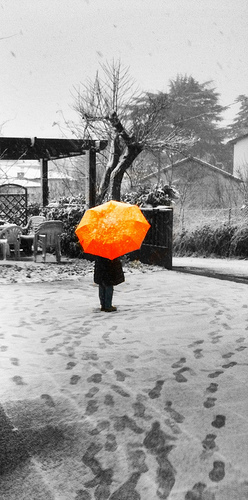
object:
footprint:
[208, 457, 227, 480]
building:
[138, 153, 243, 209]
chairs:
[1, 224, 23, 258]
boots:
[103, 303, 117, 308]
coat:
[92, 253, 125, 286]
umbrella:
[74, 197, 149, 257]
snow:
[89, 206, 125, 235]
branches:
[81, 64, 163, 145]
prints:
[208, 365, 223, 377]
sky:
[0, 1, 239, 147]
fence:
[174, 206, 246, 232]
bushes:
[172, 222, 184, 258]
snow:
[173, 255, 234, 275]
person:
[89, 254, 126, 314]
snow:
[2, 270, 239, 498]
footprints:
[111, 382, 129, 398]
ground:
[1, 256, 239, 498]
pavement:
[0, 269, 246, 498]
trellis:
[1, 185, 27, 234]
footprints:
[83, 397, 101, 419]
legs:
[101, 284, 116, 309]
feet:
[103, 304, 116, 309]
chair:
[34, 222, 62, 263]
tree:
[64, 72, 210, 212]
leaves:
[145, 95, 168, 111]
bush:
[208, 213, 225, 255]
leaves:
[216, 233, 221, 240]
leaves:
[233, 241, 240, 253]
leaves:
[224, 240, 238, 255]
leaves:
[202, 227, 225, 242]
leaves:
[216, 227, 229, 238]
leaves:
[65, 231, 72, 245]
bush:
[64, 219, 76, 254]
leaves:
[216, 233, 225, 242]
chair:
[21, 215, 45, 257]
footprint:
[148, 377, 162, 397]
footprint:
[211, 414, 227, 426]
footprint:
[12, 373, 23, 385]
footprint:
[148, 377, 166, 397]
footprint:
[187, 339, 204, 346]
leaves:
[171, 106, 186, 124]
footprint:
[201, 431, 217, 449]